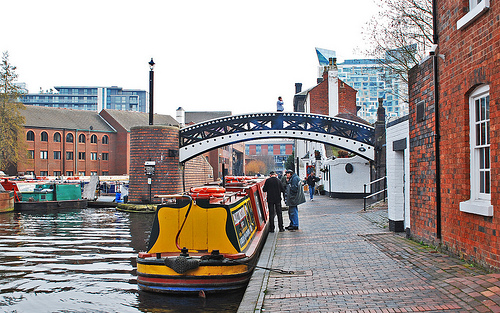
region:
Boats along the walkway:
[102, 130, 343, 277]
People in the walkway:
[240, 175, 367, 232]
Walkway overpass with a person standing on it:
[143, 49, 411, 182]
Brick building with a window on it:
[428, 23, 497, 191]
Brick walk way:
[304, 212, 384, 304]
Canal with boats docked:
[28, 230, 148, 296]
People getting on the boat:
[242, 140, 342, 242]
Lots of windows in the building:
[25, 131, 157, 198]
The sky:
[181, 25, 256, 86]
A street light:
[131, 37, 186, 132]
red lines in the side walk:
[258, 283, 456, 304]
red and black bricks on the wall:
[409, 131, 449, 193]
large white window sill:
[449, 193, 498, 224]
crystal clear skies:
[113, 10, 288, 72]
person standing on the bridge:
[270, 86, 295, 118]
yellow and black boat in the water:
[110, 172, 267, 310]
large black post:
[135, 51, 180, 125]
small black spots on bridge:
[177, 118, 352, 164]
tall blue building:
[11, 56, 176, 150]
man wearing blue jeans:
[281, 199, 321, 230]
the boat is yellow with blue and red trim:
[138, 184, 293, 293]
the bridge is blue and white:
[171, 98, 391, 175]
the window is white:
[456, 71, 498, 248]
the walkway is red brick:
[271, 256, 438, 311]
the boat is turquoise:
[13, 181, 92, 221]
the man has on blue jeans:
[278, 161, 330, 236]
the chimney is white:
[286, 61, 356, 116]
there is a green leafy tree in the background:
[1, 91, 31, 186]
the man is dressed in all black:
[248, 171, 292, 238]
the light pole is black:
[136, 59, 168, 126]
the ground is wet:
[315, 246, 389, 307]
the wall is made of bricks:
[418, 116, 447, 220]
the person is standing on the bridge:
[181, 98, 370, 140]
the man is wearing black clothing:
[256, 181, 285, 238]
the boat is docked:
[153, 184, 291, 300]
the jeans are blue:
[284, 207, 318, 237]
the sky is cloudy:
[65, 6, 263, 63]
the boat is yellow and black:
[135, 183, 275, 280]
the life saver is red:
[184, 182, 239, 212]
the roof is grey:
[33, 101, 111, 127]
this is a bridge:
[148, 105, 412, 175]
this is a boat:
[131, 179, 281, 296]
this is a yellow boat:
[133, 177, 280, 294]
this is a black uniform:
[251, 159, 288, 236]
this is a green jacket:
[274, 170, 306, 202]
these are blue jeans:
[277, 200, 307, 227]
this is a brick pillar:
[113, 111, 211, 201]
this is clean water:
[24, 157, 205, 309]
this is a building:
[9, 93, 192, 198]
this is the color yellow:
[212, 230, 217, 241]